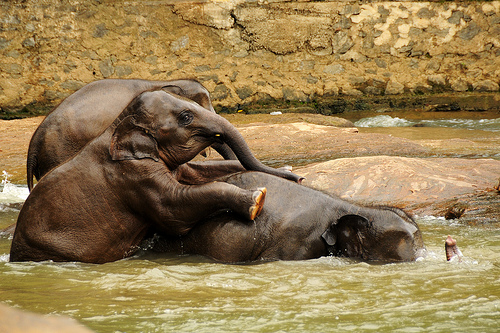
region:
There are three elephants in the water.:
[8, 79, 465, 266]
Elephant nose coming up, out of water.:
[443, 235, 462, 265]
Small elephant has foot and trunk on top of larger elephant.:
[7, 88, 305, 266]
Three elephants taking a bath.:
[7, 77, 472, 266]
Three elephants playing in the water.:
[8, 77, 465, 267]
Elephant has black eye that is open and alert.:
[175, 109, 195, 126]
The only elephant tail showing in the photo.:
[24, 149, 34, 193]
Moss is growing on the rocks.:
[225, 81, 498, 112]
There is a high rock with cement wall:
[0, 1, 499, 113]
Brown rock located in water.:
[289, 154, 498, 217]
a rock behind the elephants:
[6, 0, 458, 72]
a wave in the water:
[260, 109, 497, 143]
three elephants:
[5, 43, 437, 284]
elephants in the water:
[30, 68, 478, 287]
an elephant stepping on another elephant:
[62, 113, 403, 269]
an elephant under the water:
[215, 165, 465, 287]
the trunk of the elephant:
[210, 115, 297, 183]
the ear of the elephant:
[110, 115, 148, 155]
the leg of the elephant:
[197, 177, 267, 219]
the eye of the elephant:
[181, 110, 191, 120]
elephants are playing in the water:
[46, 58, 447, 296]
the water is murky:
[138, 264, 313, 324]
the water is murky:
[179, 273, 239, 288]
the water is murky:
[174, 271, 274, 322]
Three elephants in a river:
[6, 72, 466, 312]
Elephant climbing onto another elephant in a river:
[11, 88, 472, 283]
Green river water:
[220, 271, 388, 326]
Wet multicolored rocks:
[285, 3, 495, 112]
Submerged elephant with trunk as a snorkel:
[176, 165, 467, 290]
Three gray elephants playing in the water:
[9, 68, 483, 293]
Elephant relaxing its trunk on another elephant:
[11, 87, 320, 269]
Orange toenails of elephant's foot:
[200, 176, 289, 236]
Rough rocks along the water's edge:
[252, 5, 456, 115]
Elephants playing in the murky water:
[7, 57, 476, 325]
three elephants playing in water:
[9, 68, 463, 275]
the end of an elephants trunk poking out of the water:
[438, 230, 468, 266]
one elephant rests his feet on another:
[8, 85, 468, 282]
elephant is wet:
[9, 88, 305, 276]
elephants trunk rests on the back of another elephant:
[114, 85, 463, 276]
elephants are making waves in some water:
[2, 167, 498, 332]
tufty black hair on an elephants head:
[355, 198, 423, 229]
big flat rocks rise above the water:
[1, 107, 498, 220]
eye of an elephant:
[176, 111, 197, 124]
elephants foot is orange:
[216, 177, 268, 225]